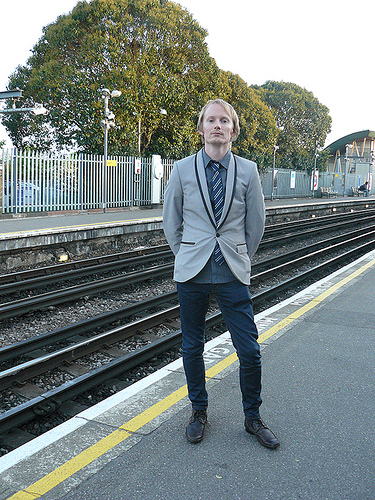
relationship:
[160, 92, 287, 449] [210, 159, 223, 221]
man wears tie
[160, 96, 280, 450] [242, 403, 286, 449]
man wears shoe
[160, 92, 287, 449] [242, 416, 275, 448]
man wears foot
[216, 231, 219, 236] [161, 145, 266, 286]
button on jacket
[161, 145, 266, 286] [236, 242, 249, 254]
jacket has pocket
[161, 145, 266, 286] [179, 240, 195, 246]
jacket has pocket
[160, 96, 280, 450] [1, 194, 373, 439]
man near train tracks